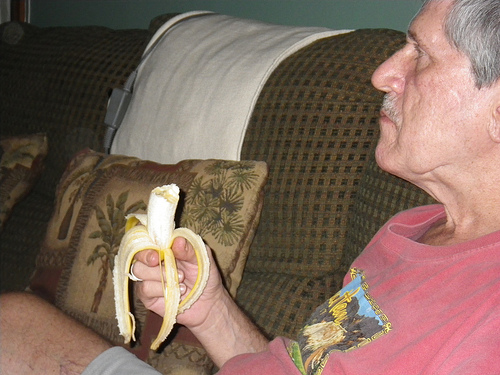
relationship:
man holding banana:
[0, 2, 499, 374] [112, 182, 211, 351]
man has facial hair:
[0, 2, 499, 374] [380, 93, 404, 135]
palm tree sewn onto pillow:
[89, 184, 152, 318] [27, 146, 267, 374]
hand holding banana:
[131, 236, 221, 326] [112, 182, 211, 351]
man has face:
[0, 2, 499, 374] [372, 0, 499, 163]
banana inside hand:
[112, 182, 211, 351] [131, 236, 221, 326]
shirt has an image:
[208, 203, 499, 373] [295, 276, 388, 374]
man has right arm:
[0, 2, 499, 374] [132, 239, 277, 368]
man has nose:
[0, 2, 499, 374] [370, 46, 407, 96]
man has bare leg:
[0, 2, 499, 374] [0, 288, 114, 374]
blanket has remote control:
[100, 7, 356, 165] [99, 84, 134, 147]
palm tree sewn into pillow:
[89, 184, 152, 318] [27, 146, 267, 374]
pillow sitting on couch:
[27, 146, 267, 374] [1, 20, 455, 373]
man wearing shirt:
[0, 2, 499, 374] [208, 203, 499, 373]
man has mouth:
[0, 2, 499, 374] [378, 106, 398, 126]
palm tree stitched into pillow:
[89, 184, 152, 318] [27, 146, 267, 374]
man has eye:
[0, 2, 499, 374] [413, 41, 429, 64]